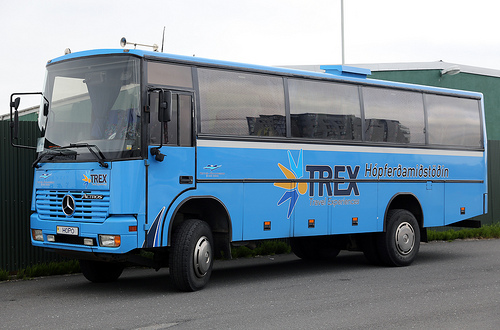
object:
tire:
[385, 209, 421, 267]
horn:
[119, 37, 158, 51]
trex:
[306, 166, 360, 196]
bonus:
[9, 38, 489, 292]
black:
[347, 165, 361, 195]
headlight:
[98, 234, 121, 248]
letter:
[364, 162, 449, 179]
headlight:
[32, 228, 43, 241]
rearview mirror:
[149, 87, 171, 162]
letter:
[306, 165, 362, 196]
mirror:
[12, 98, 21, 142]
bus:
[29, 48, 490, 292]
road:
[0, 237, 498, 328]